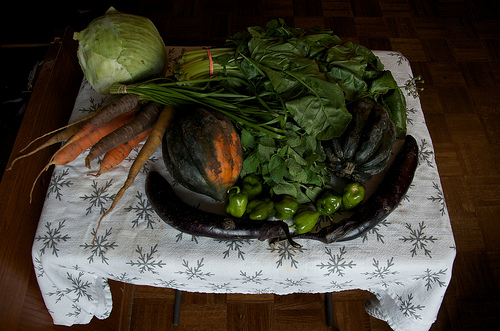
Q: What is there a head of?
A: Cabbage.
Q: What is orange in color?
A: Carrots.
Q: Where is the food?
A: On a table.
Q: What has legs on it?
A: The tray.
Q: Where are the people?
A: No people visible.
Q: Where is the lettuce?
A: Next to carrots.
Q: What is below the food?
A: Tablecloth.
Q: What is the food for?
A: Eating.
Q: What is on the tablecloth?
A: A design.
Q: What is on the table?
A: Vegetables.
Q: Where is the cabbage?
A: Beside the turnips.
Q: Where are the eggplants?
A: Beside the peppers.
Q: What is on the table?
A: A tablecloth.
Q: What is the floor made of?
A: Wood.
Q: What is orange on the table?
A: Carrots.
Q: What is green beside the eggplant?
A: Peppers.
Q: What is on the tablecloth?
A: Snowflakes.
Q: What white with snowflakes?
A: Tablecloth.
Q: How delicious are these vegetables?
A: In the present state, not very.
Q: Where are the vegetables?
A: On a plate.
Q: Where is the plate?
A: On a tablecloth.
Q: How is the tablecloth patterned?
A: With snowflakes.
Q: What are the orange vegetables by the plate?
A: Carrots.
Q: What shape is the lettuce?
A: Round.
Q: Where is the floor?
A: Under the table.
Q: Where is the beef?
A: Not in this picture.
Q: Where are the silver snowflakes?
A: On the tablecloth.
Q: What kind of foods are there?
A: Veggies.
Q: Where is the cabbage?
A: Upper left.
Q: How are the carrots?
A: Dirty.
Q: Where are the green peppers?
A: Front.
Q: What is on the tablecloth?
A: Snowflakes.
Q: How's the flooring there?
A: Wood.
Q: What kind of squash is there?
A: Acorn squash.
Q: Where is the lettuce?
A: Upper right.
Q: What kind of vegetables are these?
A: Green and leafy vegetables.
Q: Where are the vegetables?
A: On a table.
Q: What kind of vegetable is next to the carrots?
A: Green leafy vegetable.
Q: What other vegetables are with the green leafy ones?
A: Carrots, cabbage, eggplant, peppers and squash.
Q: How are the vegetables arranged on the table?
A: In a pile.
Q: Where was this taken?
A: In a kitchen.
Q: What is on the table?
A: Vegetables.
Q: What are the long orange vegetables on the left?
A: Carrots.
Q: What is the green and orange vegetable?
A: Squash.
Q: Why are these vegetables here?
A: They were just collected.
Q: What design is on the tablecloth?
A: Snowflakes.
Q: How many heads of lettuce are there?
A: One.